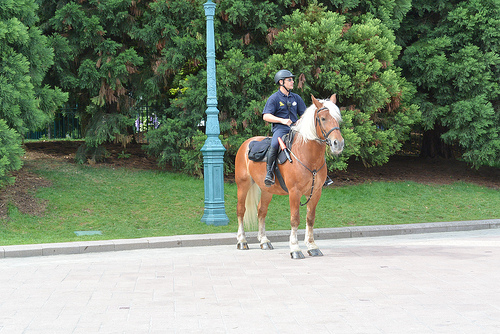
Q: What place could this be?
A: It is a street.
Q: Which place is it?
A: It is a street.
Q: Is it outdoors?
A: Yes, it is outdoors.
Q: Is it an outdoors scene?
A: Yes, it is outdoors.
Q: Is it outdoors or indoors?
A: It is outdoors.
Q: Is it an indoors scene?
A: No, it is outdoors.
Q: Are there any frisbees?
A: No, there are no frisbees.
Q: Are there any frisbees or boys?
A: No, there are no frisbees or boys.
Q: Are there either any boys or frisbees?
A: No, there are no frisbees or boys.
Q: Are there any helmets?
A: Yes, there is a helmet.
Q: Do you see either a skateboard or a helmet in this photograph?
A: Yes, there is a helmet.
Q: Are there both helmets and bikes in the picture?
A: No, there is a helmet but no bikes.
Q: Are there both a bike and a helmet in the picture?
A: No, there is a helmet but no bikes.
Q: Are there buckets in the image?
A: No, there are no buckets.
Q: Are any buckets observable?
A: No, there are no buckets.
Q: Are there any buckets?
A: No, there are no buckets.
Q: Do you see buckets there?
A: No, there are no buckets.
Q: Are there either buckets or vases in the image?
A: No, there are no buckets or vases.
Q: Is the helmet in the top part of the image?
A: Yes, the helmet is in the top of the image.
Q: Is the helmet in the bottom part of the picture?
A: No, the helmet is in the top of the image.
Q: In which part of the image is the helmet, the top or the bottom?
A: The helmet is in the top of the image.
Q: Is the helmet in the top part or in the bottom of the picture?
A: The helmet is in the top of the image.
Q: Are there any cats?
A: No, there are no cats.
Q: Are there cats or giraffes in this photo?
A: No, there are no cats or giraffes.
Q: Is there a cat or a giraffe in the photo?
A: No, there are no cats or giraffes.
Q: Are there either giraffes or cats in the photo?
A: No, there are no cats or giraffes.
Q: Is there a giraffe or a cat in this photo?
A: No, there are no cats or giraffes.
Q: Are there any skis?
A: No, there are no skis.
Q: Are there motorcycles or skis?
A: No, there are no skis or motorcycles.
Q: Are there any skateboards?
A: No, there are no skateboards.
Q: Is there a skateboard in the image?
A: No, there are no skateboards.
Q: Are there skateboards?
A: No, there are no skateboards.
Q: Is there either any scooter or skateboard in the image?
A: No, there are no skateboards or scooters.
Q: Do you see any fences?
A: Yes, there is a fence.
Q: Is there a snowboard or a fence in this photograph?
A: Yes, there is a fence.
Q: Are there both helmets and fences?
A: Yes, there are both a fence and a helmet.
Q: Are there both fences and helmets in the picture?
A: Yes, there are both a fence and a helmet.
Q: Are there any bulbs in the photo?
A: No, there are no bulbs.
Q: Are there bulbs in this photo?
A: No, there are no bulbs.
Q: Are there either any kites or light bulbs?
A: No, there are no light bulbs or kites.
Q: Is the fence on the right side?
A: No, the fence is on the left of the image.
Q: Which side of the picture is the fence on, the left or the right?
A: The fence is on the left of the image.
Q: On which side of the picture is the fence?
A: The fence is on the left of the image.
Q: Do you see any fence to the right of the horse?
A: No, the fence is to the left of the horse.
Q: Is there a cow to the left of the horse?
A: No, there is a fence to the left of the horse.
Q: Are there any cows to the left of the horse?
A: No, there is a fence to the left of the horse.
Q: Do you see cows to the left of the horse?
A: No, there is a fence to the left of the horse.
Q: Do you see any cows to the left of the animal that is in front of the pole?
A: No, there is a fence to the left of the horse.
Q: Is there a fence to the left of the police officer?
A: Yes, there is a fence to the left of the police officer.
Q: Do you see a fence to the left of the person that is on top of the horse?
A: Yes, there is a fence to the left of the police officer.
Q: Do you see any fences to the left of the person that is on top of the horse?
A: Yes, there is a fence to the left of the police officer.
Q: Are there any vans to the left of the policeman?
A: No, there is a fence to the left of the policeman.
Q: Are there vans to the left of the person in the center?
A: No, there is a fence to the left of the policeman.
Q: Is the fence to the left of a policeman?
A: Yes, the fence is to the left of a policeman.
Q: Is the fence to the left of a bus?
A: No, the fence is to the left of a policeman.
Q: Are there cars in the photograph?
A: No, there are no cars.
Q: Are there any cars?
A: No, there are no cars.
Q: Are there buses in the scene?
A: No, there are no buses.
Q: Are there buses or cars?
A: No, there are no buses or cars.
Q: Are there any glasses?
A: No, there are no glasses.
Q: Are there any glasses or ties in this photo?
A: No, there are no glasses or ties.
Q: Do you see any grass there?
A: Yes, there is grass.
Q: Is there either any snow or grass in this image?
A: Yes, there is grass.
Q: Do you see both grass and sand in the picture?
A: No, there is grass but no sand.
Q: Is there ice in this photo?
A: No, there is no ice.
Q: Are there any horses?
A: Yes, there is a horse.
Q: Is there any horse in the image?
A: Yes, there is a horse.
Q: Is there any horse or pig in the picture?
A: Yes, there is a horse.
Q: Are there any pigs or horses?
A: Yes, there is a horse.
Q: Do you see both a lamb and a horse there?
A: No, there is a horse but no lambs.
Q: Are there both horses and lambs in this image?
A: No, there is a horse but no lambs.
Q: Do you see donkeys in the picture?
A: No, there are no donkeys.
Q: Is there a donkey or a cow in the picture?
A: No, there are no donkeys or cows.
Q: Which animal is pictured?
A: The animal is a horse.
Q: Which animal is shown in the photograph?
A: The animal is a horse.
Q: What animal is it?
A: The animal is a horse.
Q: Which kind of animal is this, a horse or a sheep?
A: This is a horse.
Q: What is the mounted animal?
A: The animal is a horse.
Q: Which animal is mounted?
A: The animal is a horse.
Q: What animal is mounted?
A: The animal is a horse.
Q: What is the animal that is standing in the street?
A: The animal is a horse.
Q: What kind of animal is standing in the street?
A: The animal is a horse.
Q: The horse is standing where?
A: The horse is standing in the street.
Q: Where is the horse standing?
A: The horse is standing in the street.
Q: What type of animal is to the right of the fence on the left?
A: The animal is a horse.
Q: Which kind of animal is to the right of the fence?
A: The animal is a horse.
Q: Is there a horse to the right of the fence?
A: Yes, there is a horse to the right of the fence.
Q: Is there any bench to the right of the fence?
A: No, there is a horse to the right of the fence.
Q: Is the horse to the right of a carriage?
A: No, the horse is to the right of the fence.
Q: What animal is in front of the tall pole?
A: The horse is in front of the pole.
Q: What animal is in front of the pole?
A: The horse is in front of the pole.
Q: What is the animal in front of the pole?
A: The animal is a horse.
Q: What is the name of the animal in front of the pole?
A: The animal is a horse.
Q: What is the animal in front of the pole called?
A: The animal is a horse.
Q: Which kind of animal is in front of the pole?
A: The animal is a horse.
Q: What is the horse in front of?
A: The horse is in front of the pole.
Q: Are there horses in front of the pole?
A: Yes, there is a horse in front of the pole.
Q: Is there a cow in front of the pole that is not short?
A: No, there is a horse in front of the pole.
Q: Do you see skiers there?
A: No, there are no skiers.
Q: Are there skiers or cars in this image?
A: No, there are no skiers or cars.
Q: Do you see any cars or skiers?
A: No, there are no skiers or cars.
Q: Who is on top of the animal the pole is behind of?
A: The police officer is on top of the horse.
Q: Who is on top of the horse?
A: The police officer is on top of the horse.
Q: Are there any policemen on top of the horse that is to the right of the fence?
A: Yes, there is a policeman on top of the horse.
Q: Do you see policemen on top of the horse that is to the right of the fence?
A: Yes, there is a policeman on top of the horse.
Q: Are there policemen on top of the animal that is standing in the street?
A: Yes, there is a policeman on top of the horse.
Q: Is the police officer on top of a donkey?
A: No, the police officer is on top of the horse.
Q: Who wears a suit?
A: The policeman wears a suit.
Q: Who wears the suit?
A: The policeman wears a suit.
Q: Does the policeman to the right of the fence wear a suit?
A: Yes, the policeman wears a suit.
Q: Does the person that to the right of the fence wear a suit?
A: Yes, the policeman wears a suit.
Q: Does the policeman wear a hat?
A: No, the policeman wears a suit.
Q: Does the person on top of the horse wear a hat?
A: No, the policeman wears a suit.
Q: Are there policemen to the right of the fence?
A: Yes, there is a policeman to the right of the fence.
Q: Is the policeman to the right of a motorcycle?
A: No, the policeman is to the right of the fence.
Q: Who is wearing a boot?
A: The policeman is wearing a boot.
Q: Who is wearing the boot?
A: The policeman is wearing a boot.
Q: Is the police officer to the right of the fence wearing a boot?
A: Yes, the policeman is wearing a boot.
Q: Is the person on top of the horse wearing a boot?
A: Yes, the policeman is wearing a boot.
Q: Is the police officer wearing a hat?
A: No, the police officer is wearing a boot.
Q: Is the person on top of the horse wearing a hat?
A: No, the police officer is wearing a boot.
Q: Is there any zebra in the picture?
A: No, there are no zebras.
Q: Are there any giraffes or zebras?
A: No, there are no zebras or giraffes.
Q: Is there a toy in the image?
A: No, there are no toys.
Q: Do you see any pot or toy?
A: No, there are no toys or pots.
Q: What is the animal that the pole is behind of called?
A: The animal is a horse.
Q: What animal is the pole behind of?
A: The pole is behind the horse.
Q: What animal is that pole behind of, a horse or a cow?
A: The pole is behind a horse.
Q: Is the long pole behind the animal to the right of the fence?
A: Yes, the pole is behind the horse.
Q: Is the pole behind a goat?
A: No, the pole is behind the horse.